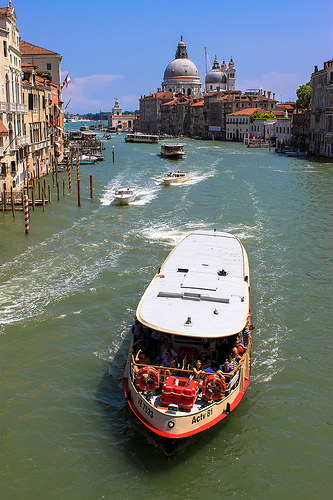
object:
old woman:
[189, 354, 207, 380]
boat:
[121, 212, 261, 457]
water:
[0, 120, 332, 495]